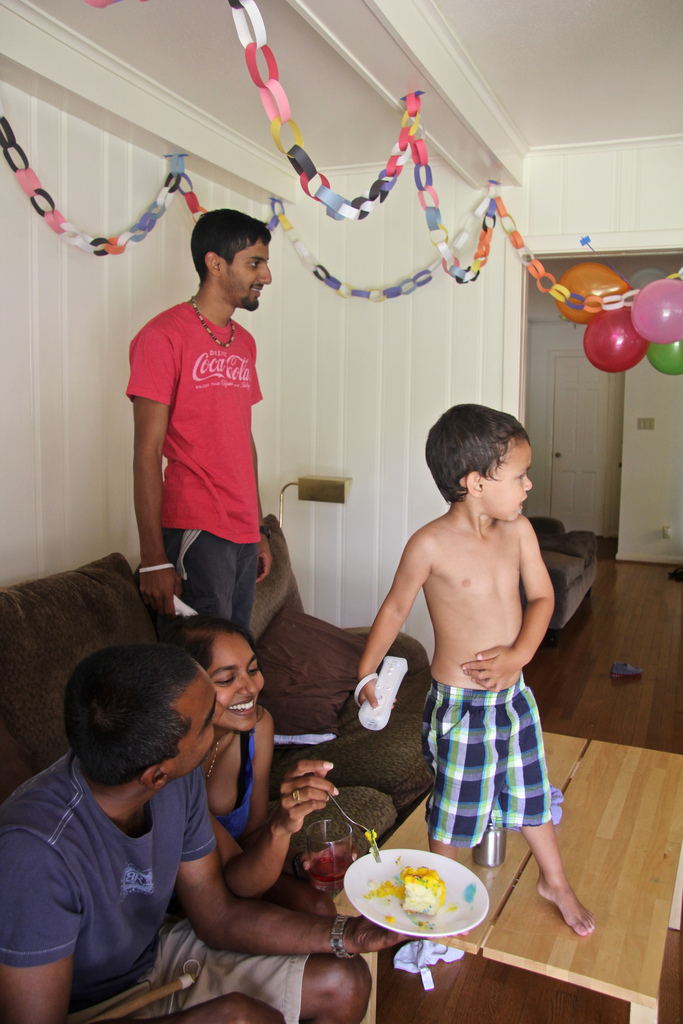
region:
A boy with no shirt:
[353, 402, 574, 835]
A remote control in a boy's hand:
[361, 650, 411, 730]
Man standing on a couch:
[130, 207, 273, 615]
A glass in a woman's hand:
[305, 825, 353, 885]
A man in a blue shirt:
[5, 667, 228, 1021]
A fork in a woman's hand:
[329, 799, 381, 859]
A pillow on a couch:
[251, 607, 354, 739]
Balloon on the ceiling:
[552, 260, 680, 375]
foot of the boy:
[540, 883, 585, 933]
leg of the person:
[525, 835, 589, 894]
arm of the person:
[361, 559, 426, 649]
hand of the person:
[474, 638, 516, 692]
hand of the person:
[350, 643, 386, 707]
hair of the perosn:
[429, 408, 488, 466]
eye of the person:
[507, 469, 525, 481]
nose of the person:
[513, 480, 532, 493]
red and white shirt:
[127, 294, 276, 542]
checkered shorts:
[418, 677, 572, 849]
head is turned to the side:
[59, 644, 223, 800]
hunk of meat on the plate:
[399, 866, 450, 915]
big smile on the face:
[225, 694, 254, 714]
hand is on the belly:
[457, 635, 533, 699]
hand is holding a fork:
[270, 751, 386, 862]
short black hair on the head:
[50, 647, 195, 792]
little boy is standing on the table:
[353, 406, 675, 1022]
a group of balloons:
[554, 256, 682, 382]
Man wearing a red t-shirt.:
[125, 207, 273, 633]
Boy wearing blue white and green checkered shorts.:
[352, 401, 600, 936]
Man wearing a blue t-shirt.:
[1, 634, 376, 1022]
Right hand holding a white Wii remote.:
[352, 647, 410, 733]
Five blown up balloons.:
[556, 264, 681, 377]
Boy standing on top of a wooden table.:
[349, 399, 676, 1022]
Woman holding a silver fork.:
[185, 613, 380, 916]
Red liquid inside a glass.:
[302, 817, 354, 895]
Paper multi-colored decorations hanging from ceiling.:
[2, 0, 679, 307]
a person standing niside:
[415, 417, 632, 888]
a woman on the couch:
[177, 610, 261, 789]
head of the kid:
[381, 405, 588, 540]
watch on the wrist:
[307, 899, 369, 976]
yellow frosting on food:
[394, 854, 464, 903]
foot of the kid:
[497, 819, 646, 975]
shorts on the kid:
[395, 656, 595, 858]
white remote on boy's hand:
[338, 649, 433, 743]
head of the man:
[56, 626, 243, 816]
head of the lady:
[188, 601, 321, 740]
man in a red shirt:
[48, 182, 357, 543]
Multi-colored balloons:
[549, 254, 679, 381]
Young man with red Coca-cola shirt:
[120, 201, 287, 633]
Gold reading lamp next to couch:
[271, 469, 361, 531]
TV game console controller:
[349, 649, 416, 737]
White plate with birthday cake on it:
[336, 844, 494, 943]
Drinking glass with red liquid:
[295, 807, 361, 898]